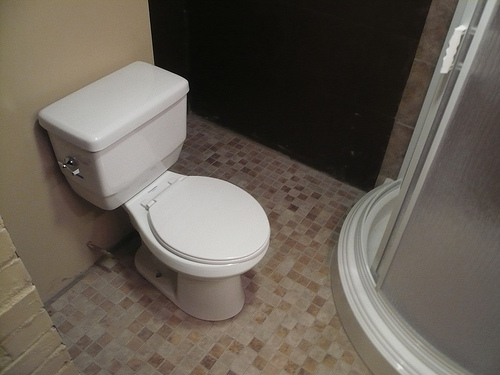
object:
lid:
[148, 175, 270, 262]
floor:
[267, 154, 302, 193]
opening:
[151, 0, 442, 193]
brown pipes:
[87, 241, 114, 259]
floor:
[280, 267, 320, 291]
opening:
[15, 251, 22, 258]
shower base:
[375, 183, 499, 374]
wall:
[0, 291, 41, 374]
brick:
[1, 221, 77, 374]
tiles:
[255, 169, 278, 186]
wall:
[90, 0, 148, 39]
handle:
[57, 157, 79, 176]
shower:
[405, 42, 493, 138]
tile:
[75, 298, 99, 317]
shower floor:
[413, 229, 499, 307]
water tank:
[37, 60, 189, 210]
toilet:
[0, 0, 498, 372]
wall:
[28, 14, 60, 34]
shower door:
[397, 2, 500, 375]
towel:
[438, 24, 471, 75]